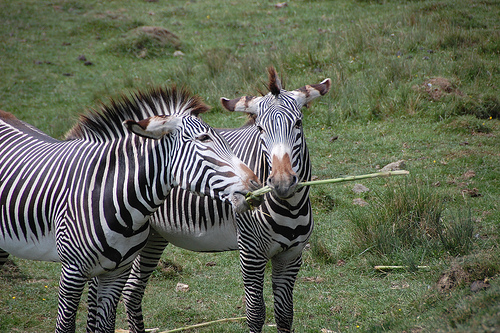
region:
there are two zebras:
[11, 57, 366, 323]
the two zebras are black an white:
[3, 44, 415, 277]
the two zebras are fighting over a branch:
[191, 142, 446, 232]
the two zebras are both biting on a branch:
[206, 151, 416, 219]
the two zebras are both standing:
[43, 64, 365, 324]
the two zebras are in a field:
[15, 42, 470, 286]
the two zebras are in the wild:
[48, 60, 479, 280]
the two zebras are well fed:
[16, 58, 365, 277]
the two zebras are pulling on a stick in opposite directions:
[96, 69, 371, 293]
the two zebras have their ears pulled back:
[97, 45, 399, 160]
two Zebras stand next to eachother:
[1, 65, 341, 325]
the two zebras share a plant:
[196, 156, 420, 220]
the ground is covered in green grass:
[13, 8, 482, 309]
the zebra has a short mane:
[63, 83, 205, 138]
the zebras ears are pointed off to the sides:
[211, 73, 350, 115]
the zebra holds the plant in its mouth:
[268, 157, 309, 204]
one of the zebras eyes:
[194, 125, 214, 149]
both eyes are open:
[255, 115, 308, 140]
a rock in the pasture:
[367, 152, 429, 195]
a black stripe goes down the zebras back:
[1, 109, 91, 159]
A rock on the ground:
[381, 159, 406, 172]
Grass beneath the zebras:
[0, 0, 496, 330]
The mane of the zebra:
[75, 87, 201, 137]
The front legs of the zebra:
[240, 245, 295, 330]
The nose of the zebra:
[261, 175, 291, 185]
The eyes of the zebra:
[256, 117, 301, 132]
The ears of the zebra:
[221, 77, 333, 113]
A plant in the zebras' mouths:
[248, 167, 407, 199]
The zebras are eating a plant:
[0, 67, 330, 332]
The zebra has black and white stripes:
[0, 89, 261, 328]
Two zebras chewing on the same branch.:
[12, 53, 420, 295]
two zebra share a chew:
[0, 41, 419, 330]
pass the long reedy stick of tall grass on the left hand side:
[228, 149, 417, 224]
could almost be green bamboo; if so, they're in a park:
[227, 166, 419, 211]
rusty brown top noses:
[230, 145, 300, 189]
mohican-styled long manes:
[57, 59, 290, 141]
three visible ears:
[118, 76, 348, 149]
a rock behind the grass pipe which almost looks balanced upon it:
[367, 154, 412, 179]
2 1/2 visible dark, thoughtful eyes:
[193, 111, 313, 147]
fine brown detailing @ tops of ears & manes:
[0, 74, 420, 148]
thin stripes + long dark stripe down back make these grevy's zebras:
[0, 95, 303, 330]